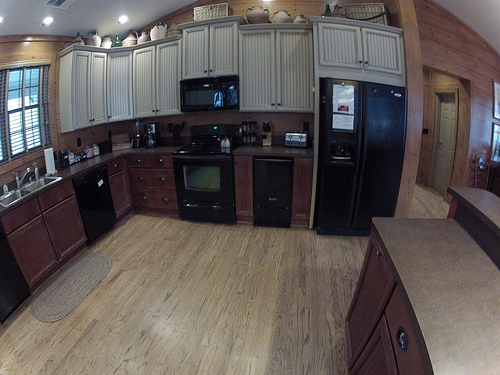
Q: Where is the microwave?
A: Above the stove.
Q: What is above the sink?
A: A window.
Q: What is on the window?
A: Blinds.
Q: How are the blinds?
A: Open.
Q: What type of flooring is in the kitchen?
A: Wood.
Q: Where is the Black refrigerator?
A: In kitchen.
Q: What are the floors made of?
A: Wood.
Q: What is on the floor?
A: A rug.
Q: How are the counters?
A: Brownish gray.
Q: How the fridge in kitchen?
A: It is black.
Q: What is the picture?
A: A black refrigerator freezer.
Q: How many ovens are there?
A: One.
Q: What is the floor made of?
A: Wood.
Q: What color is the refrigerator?
A: Black.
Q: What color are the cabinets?
A: Gray.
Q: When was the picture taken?
A: Daytime.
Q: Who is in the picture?
A: Nobody.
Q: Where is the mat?
A: By the sink.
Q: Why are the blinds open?
A: To let the sunlight in.